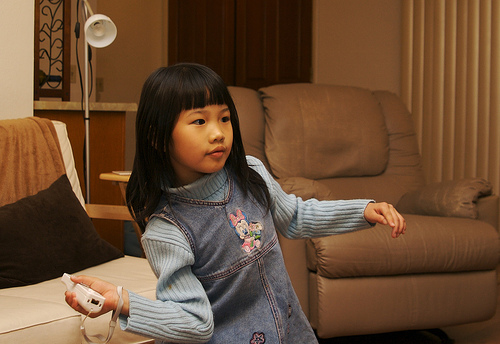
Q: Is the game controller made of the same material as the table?
A: No, the game controller is made of plastic and the table is made of wood.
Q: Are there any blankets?
A: Yes, there is a blanket.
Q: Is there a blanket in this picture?
A: Yes, there is a blanket.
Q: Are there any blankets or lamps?
A: Yes, there is a blanket.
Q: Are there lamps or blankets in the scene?
A: Yes, there is a blanket.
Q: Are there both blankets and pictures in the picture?
A: No, there is a blanket but no pictures.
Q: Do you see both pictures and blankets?
A: No, there is a blanket but no pictures.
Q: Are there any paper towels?
A: No, there are no paper towels.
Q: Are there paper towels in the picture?
A: No, there are no paper towels.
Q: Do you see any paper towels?
A: No, there are no paper towels.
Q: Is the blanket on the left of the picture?
A: Yes, the blanket is on the left of the image.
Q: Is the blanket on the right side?
A: No, the blanket is on the left of the image.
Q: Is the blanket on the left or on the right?
A: The blanket is on the left of the image.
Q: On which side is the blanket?
A: The blanket is on the left of the image.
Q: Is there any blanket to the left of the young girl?
A: Yes, there is a blanket to the left of the girl.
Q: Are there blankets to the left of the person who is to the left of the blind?
A: Yes, there is a blanket to the left of the girl.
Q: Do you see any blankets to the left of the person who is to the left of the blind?
A: Yes, there is a blanket to the left of the girl.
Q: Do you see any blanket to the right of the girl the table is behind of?
A: No, the blanket is to the left of the girl.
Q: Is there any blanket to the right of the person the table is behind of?
A: No, the blanket is to the left of the girl.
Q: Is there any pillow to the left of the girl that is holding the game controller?
A: No, there is a blanket to the left of the girl.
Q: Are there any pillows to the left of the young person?
A: No, there is a blanket to the left of the girl.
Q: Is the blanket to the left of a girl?
A: Yes, the blanket is to the left of a girl.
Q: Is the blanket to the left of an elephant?
A: No, the blanket is to the left of a girl.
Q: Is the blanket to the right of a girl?
A: No, the blanket is to the left of a girl.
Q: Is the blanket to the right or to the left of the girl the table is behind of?
A: The blanket is to the left of the girl.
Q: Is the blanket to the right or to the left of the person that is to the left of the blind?
A: The blanket is to the left of the girl.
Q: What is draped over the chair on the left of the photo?
A: The blanket is draped over the chair.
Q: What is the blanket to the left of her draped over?
A: The blanket is draped over the chair.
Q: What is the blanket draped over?
A: The blanket is draped over the chair.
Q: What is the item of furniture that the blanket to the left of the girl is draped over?
A: The piece of furniture is a chair.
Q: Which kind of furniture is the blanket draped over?
A: The blanket is draped over the chair.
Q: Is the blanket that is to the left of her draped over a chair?
A: Yes, the blanket is draped over a chair.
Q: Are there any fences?
A: No, there are no fences.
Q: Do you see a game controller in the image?
A: Yes, there is a game controller.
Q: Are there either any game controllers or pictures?
A: Yes, there is a game controller.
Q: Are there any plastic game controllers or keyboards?
A: Yes, there is a plastic game controller.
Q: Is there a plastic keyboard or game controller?
A: Yes, there is a plastic game controller.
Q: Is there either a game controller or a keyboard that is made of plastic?
A: Yes, the game controller is made of plastic.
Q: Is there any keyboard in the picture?
A: No, there are no keyboards.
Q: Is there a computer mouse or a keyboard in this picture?
A: No, there are no keyboards or computer mice.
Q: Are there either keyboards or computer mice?
A: No, there are no keyboards or computer mice.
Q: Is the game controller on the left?
A: Yes, the game controller is on the left of the image.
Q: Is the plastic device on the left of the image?
A: Yes, the game controller is on the left of the image.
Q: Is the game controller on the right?
A: No, the game controller is on the left of the image.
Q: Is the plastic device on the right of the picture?
A: No, the game controller is on the left of the image.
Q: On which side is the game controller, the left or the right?
A: The game controller is on the left of the image.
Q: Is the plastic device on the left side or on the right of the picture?
A: The game controller is on the left of the image.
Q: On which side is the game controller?
A: The game controller is on the left of the image.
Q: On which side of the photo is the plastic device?
A: The game controller is on the left of the image.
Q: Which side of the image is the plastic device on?
A: The game controller is on the left of the image.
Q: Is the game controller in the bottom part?
A: Yes, the game controller is in the bottom of the image.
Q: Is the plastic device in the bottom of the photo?
A: Yes, the game controller is in the bottom of the image.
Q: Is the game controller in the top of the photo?
A: No, the game controller is in the bottom of the image.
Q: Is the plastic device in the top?
A: No, the game controller is in the bottom of the image.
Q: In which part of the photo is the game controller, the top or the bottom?
A: The game controller is in the bottom of the image.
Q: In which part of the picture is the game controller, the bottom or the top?
A: The game controller is in the bottom of the image.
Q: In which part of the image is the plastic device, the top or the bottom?
A: The game controller is in the bottom of the image.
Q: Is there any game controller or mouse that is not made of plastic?
A: No, there is a game controller but it is made of plastic.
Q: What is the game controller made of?
A: The game controller is made of plastic.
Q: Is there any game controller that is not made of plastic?
A: No, there is a game controller but it is made of plastic.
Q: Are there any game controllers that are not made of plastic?
A: No, there is a game controller but it is made of plastic.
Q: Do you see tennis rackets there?
A: No, there are no tennis rackets.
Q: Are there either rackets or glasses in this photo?
A: No, there are no rackets or glasses.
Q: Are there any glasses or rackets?
A: No, there are no rackets or glasses.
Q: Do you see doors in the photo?
A: Yes, there are doors.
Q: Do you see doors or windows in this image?
A: Yes, there are doors.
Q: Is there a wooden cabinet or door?
A: Yes, there are wood doors.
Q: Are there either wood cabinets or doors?
A: Yes, there are wood doors.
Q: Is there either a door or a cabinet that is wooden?
A: Yes, the doors are wooden.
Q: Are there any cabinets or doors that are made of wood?
A: Yes, the doors are made of wood.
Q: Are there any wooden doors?
A: Yes, there are wood doors.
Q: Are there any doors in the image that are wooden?
A: Yes, there are doors that are wooden.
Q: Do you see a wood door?
A: Yes, there are doors that are made of wood.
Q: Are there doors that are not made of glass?
A: Yes, there are doors that are made of wood.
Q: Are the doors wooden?
A: Yes, the doors are wooden.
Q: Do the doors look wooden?
A: Yes, the doors are wooden.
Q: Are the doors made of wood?
A: Yes, the doors are made of wood.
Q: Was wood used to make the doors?
A: Yes, the doors are made of wood.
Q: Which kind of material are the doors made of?
A: The doors are made of wood.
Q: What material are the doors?
A: The doors are made of wood.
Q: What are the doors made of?
A: The doors are made of wood.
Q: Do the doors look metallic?
A: No, the doors are wooden.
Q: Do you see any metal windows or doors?
A: No, there are doors but they are wooden.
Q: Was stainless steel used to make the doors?
A: No, the doors are made of wood.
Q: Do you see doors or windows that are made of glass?
A: No, there are doors but they are made of wood.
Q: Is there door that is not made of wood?
A: No, there are doors but they are made of wood.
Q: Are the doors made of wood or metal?
A: The doors are made of wood.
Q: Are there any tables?
A: Yes, there is a table.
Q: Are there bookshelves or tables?
A: Yes, there is a table.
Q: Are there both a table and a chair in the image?
A: Yes, there are both a table and a chair.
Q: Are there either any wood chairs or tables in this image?
A: Yes, there is a wood table.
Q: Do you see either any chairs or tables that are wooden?
A: Yes, the table is wooden.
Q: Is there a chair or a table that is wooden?
A: Yes, the table is wooden.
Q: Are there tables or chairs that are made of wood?
A: Yes, the table is made of wood.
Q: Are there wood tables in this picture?
A: Yes, there is a wood table.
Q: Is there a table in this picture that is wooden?
A: Yes, there is a table that is wooden.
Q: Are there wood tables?
A: Yes, there is a table that is made of wood.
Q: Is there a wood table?
A: Yes, there is a table that is made of wood.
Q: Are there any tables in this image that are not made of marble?
A: Yes, there is a table that is made of wood.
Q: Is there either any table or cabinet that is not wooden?
A: No, there is a table but it is wooden.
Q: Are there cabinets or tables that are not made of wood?
A: No, there is a table but it is made of wood.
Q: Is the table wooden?
A: Yes, the table is wooden.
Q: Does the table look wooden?
A: Yes, the table is wooden.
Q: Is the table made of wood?
A: Yes, the table is made of wood.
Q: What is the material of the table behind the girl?
A: The table is made of wood.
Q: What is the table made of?
A: The table is made of wood.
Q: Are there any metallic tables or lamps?
A: No, there is a table but it is wooden.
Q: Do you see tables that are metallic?
A: No, there is a table but it is wooden.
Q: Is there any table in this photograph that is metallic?
A: No, there is a table but it is wooden.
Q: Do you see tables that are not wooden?
A: No, there is a table but it is wooden.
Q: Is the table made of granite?
A: No, the table is made of wood.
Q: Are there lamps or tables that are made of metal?
A: No, there is a table but it is made of wood.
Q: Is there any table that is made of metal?
A: No, there is a table but it is made of wood.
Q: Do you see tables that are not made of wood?
A: No, there is a table but it is made of wood.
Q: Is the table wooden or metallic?
A: The table is wooden.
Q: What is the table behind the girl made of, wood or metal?
A: The table is made of wood.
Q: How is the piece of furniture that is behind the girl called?
A: The piece of furniture is a table.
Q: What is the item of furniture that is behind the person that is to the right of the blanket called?
A: The piece of furniture is a table.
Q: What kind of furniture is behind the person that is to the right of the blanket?
A: The piece of furniture is a table.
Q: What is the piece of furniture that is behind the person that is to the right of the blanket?
A: The piece of furniture is a table.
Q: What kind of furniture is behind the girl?
A: The piece of furniture is a table.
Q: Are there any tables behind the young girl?
A: Yes, there is a table behind the girl.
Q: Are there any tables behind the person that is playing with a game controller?
A: Yes, there is a table behind the girl.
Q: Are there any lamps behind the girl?
A: No, there is a table behind the girl.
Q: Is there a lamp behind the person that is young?
A: No, there is a table behind the girl.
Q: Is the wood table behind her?
A: Yes, the table is behind a girl.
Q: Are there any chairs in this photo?
A: Yes, there is a chair.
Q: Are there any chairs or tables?
A: Yes, there is a chair.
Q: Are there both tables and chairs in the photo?
A: Yes, there are both a chair and a table.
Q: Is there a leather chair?
A: Yes, there is a chair that is made of leather.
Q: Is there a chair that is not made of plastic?
A: Yes, there is a chair that is made of leather.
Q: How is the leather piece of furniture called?
A: The piece of furniture is a chair.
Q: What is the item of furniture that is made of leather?
A: The piece of furniture is a chair.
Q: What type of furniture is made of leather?
A: The furniture is a chair.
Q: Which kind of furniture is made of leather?
A: The furniture is a chair.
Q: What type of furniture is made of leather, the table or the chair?
A: The chair is made of leather.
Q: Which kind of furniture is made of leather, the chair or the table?
A: The chair is made of leather.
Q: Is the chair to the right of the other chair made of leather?
A: Yes, the chair is made of leather.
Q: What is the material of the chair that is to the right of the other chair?
A: The chair is made of leather.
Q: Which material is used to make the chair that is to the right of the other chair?
A: The chair is made of leather.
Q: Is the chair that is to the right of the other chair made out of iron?
A: No, the chair is made of leather.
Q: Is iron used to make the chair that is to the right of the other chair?
A: No, the chair is made of leather.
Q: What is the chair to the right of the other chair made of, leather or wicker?
A: The chair is made of leather.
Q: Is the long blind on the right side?
A: Yes, the blind is on the right of the image.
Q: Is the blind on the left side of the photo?
A: No, the blind is on the right of the image.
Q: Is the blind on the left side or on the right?
A: The blind is on the right of the image.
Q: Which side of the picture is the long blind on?
A: The blind is on the right of the image.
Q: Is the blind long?
A: Yes, the blind is long.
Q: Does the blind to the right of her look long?
A: Yes, the blind is long.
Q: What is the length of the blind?
A: The blind is long.